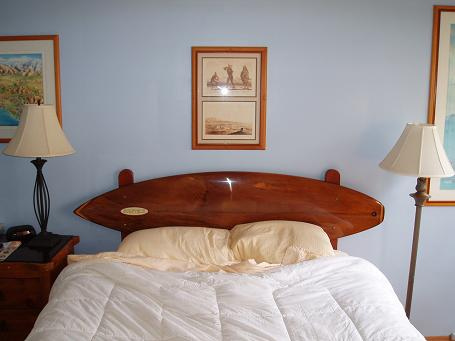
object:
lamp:
[0, 100, 76, 244]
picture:
[189, 45, 268, 154]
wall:
[0, 1, 455, 341]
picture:
[1, 38, 57, 139]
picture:
[428, 4, 454, 206]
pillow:
[117, 225, 229, 269]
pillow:
[229, 218, 334, 265]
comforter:
[20, 255, 429, 340]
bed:
[23, 167, 429, 340]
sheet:
[65, 252, 284, 274]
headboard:
[72, 168, 385, 251]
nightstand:
[1, 232, 80, 341]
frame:
[189, 45, 266, 152]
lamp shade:
[0, 103, 76, 159]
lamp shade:
[378, 120, 455, 180]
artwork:
[200, 56, 257, 141]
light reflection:
[214, 176, 238, 194]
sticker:
[121, 205, 148, 216]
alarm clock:
[4, 223, 35, 240]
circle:
[370, 210, 379, 218]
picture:
[201, 54, 258, 99]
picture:
[201, 100, 257, 140]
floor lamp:
[378, 121, 455, 319]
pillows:
[117, 218, 336, 264]